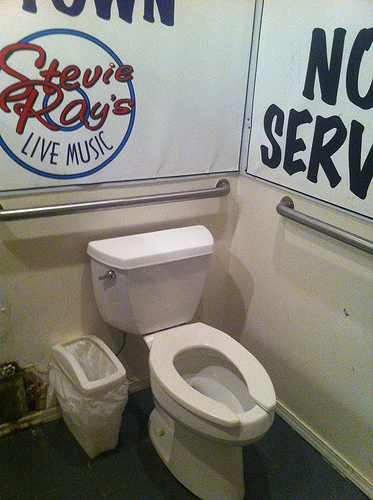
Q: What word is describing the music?
A: Live.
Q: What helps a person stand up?
A: Hand rails.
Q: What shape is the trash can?
A: Rectangular.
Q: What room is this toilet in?
A: A bathroom?.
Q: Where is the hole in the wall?
A: By the trash can.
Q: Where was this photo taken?
A: In a bathroom.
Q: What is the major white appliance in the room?
A: The toilet.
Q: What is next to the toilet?
A: A garbage can.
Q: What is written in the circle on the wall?
A: Stevie Ray's LIVE MUSIC.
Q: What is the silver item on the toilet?
A: The flush handle.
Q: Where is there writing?
A: On signs on the walls.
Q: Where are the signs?
A: On the walls.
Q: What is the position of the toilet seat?
A: It's down.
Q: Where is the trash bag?
A: In the trash can.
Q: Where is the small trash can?
A: Near toilet.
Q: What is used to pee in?
A: Toilet.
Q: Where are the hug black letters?
A: On wall.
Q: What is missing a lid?
A: Toilet.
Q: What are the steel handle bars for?
A: Handicapped helper.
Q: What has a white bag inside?
A: Trash can.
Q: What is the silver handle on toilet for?
A: Flushing.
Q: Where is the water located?
A: In toilet.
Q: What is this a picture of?
A: A white toilet.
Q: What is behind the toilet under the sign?
A: A hand rail.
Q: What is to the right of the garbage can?
A: A toilet.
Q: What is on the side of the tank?
A: A silver handle.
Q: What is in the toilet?
A: Water.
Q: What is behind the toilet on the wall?
A: A sign.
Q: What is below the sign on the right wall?
A: A handrail.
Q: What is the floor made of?
A: Dirty blue carpet.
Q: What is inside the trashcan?
A: A white trashbag.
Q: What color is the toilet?
A: White.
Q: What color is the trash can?
A: White.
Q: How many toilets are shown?
A: 1.